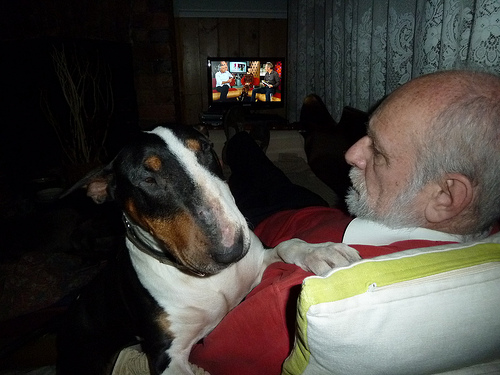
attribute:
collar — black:
[119, 212, 197, 278]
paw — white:
[277, 234, 362, 282]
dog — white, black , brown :
[59, 120, 361, 374]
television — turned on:
[203, 53, 288, 106]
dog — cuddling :
[104, 120, 259, 320]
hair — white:
[347, 98, 495, 217]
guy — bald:
[334, 71, 487, 256]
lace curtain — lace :
[288, 2, 498, 119]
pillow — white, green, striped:
[271, 267, 493, 369]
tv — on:
[209, 61, 280, 103]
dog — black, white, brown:
[64, 114, 263, 311]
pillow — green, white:
[281, 234, 498, 374]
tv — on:
[187, 50, 314, 111]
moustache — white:
[346, 164, 371, 206]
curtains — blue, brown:
[283, 2, 495, 129]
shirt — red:
[188, 205, 498, 374]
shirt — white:
[213, 69, 233, 90]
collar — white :
[337, 209, 497, 249]